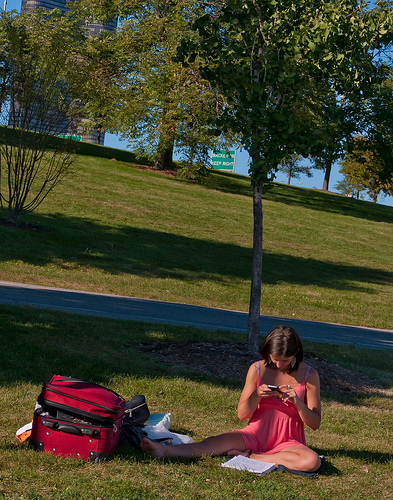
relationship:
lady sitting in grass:
[140, 326, 322, 473] [3, 303, 383, 496]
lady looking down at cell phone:
[140, 326, 322, 473] [268, 385, 279, 390]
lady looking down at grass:
[140, 326, 322, 473] [0, 124, 388, 492]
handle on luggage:
[53, 418, 83, 438] [17, 362, 155, 449]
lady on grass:
[148, 325, 377, 494] [0, 124, 388, 492]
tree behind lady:
[200, 0, 383, 355] [148, 325, 377, 494]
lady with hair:
[140, 326, 322, 473] [262, 322, 304, 372]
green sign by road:
[202, 140, 237, 180] [126, 129, 295, 161]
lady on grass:
[140, 326, 322, 473] [0, 124, 388, 492]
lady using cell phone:
[140, 326, 322, 473] [268, 385, 279, 390]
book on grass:
[220, 453, 275, 476] [0, 124, 388, 492]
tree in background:
[200, 6, 383, 338] [2, 2, 392, 208]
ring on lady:
[283, 384, 293, 391] [140, 326, 322, 473]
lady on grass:
[140, 326, 322, 473] [6, 129, 389, 347]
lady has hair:
[140, 326, 322, 473] [253, 316, 306, 369]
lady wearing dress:
[140, 326, 322, 473] [240, 358, 314, 446]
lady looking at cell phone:
[140, 326, 322, 473] [262, 378, 282, 395]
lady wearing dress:
[140, 326, 322, 473] [228, 363, 312, 455]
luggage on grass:
[30, 374, 151, 457] [36, 302, 356, 414]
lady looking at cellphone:
[140, 326, 322, 473] [261, 379, 287, 399]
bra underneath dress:
[246, 359, 313, 394] [212, 330, 325, 479]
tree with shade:
[200, 0, 383, 355] [2, 305, 391, 404]